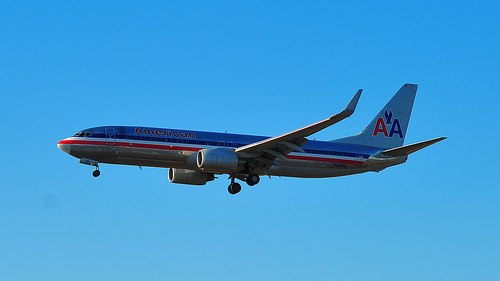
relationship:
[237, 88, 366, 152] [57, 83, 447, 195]
wing on plane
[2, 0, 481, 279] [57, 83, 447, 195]
sky above plane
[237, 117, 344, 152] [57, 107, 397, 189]
wing attached plane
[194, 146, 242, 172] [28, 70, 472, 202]
engine attached plane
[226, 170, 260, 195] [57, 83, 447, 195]
landing gear attached plane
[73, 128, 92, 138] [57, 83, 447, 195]
windows attached plane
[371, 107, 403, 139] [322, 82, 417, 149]
logo attached tail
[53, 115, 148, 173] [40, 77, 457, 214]
front of plane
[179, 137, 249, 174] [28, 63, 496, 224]
turbine of plane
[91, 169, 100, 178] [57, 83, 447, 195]
small wheel of plane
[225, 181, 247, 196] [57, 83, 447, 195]
wheel of plane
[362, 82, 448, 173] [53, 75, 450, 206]
tail of plane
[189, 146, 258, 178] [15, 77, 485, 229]
engine on side of plane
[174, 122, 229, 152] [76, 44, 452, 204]
window on plane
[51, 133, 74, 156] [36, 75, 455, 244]
nose on plane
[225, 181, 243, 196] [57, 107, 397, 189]
wheel on plane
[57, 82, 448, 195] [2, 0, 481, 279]
airplane in sky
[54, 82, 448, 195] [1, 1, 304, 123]
airplane through sky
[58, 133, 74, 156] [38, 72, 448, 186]
nose of plane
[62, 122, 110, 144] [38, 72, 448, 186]
cockpit of plane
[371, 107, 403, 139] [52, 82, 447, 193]
logo of carrier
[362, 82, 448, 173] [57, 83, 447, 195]
tail of plane